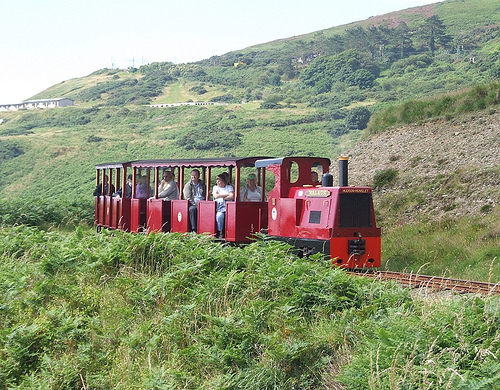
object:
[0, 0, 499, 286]
hillside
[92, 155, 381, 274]
train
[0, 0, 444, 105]
sky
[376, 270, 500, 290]
tracks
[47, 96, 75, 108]
houses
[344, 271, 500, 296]
tracks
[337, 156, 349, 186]
black funnel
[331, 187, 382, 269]
front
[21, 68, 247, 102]
hill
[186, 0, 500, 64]
hill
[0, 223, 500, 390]
grass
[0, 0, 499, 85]
distance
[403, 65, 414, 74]
trees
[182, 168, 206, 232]
man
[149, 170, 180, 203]
man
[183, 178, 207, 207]
jacket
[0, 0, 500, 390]
land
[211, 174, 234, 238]
passenger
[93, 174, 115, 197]
passenger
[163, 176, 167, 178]
shades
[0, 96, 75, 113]
building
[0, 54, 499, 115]
countryside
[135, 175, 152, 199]
person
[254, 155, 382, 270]
engine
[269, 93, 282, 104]
tree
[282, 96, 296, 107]
tree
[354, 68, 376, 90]
tree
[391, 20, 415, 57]
tree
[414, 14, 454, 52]
tree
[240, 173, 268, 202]
people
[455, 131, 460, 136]
rocks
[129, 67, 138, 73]
trees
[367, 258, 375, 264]
holes